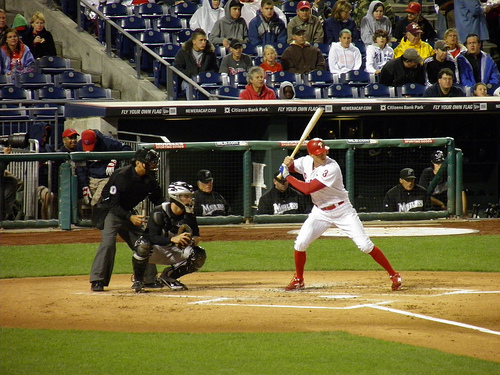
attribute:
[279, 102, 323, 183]
bat — brown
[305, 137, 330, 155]
helmet — red, plastic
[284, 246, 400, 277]
socks — high, red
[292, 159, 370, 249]
uniform — white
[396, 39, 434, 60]
shirt — yellow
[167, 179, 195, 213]
helmet — white, black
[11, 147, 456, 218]
fence — green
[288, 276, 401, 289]
shoes — red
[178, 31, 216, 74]
person — sitting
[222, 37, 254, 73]
person — sitting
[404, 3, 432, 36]
person — sitting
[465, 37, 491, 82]
person — sitting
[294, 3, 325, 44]
person — sitting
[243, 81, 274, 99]
hoodie — red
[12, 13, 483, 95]
seats — blue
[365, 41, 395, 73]
sweatshirt — white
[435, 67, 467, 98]
man — watching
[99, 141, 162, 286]
umpire — waiting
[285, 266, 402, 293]
sneakers — white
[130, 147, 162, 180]
helmet — black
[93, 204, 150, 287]
pants — grey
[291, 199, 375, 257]
pants — white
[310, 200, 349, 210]
belt — red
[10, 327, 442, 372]
grass — green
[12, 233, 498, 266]
grass — green